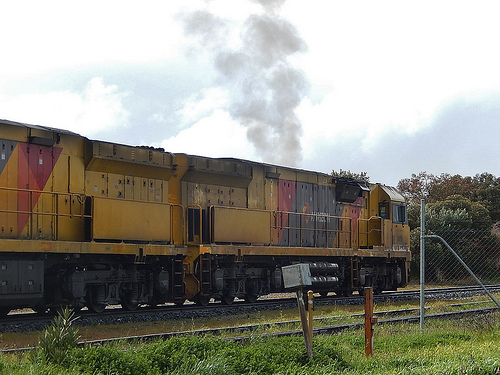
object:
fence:
[416, 196, 500, 329]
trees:
[437, 207, 477, 282]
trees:
[397, 168, 431, 197]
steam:
[241, 12, 318, 162]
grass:
[1, 298, 500, 374]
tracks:
[2, 296, 499, 360]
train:
[0, 116, 416, 317]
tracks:
[0, 282, 500, 328]